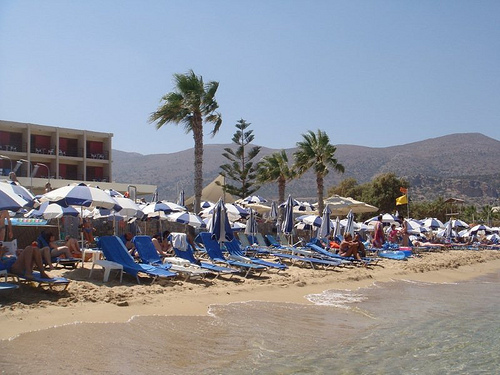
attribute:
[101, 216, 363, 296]
chairs — empty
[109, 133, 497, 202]
land — distant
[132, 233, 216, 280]
chair — blue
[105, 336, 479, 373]
water — clear, calm, shallow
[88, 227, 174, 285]
chair — blue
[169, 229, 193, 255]
towel — white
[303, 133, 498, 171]
mountain — large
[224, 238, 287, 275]
chair — blue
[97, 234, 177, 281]
beach chair — blue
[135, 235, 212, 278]
beach chair — blue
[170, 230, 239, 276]
beach chair — blue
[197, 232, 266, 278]
beach chair — blue, empty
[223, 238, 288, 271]
beach chair — blue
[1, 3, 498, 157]
sky — blue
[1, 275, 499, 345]
foam — white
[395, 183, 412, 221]
flag — yellow, red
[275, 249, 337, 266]
beach chair — blue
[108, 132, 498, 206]
mountain — brown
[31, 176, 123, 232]
parasol — blue, white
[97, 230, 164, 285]
beach chair — empty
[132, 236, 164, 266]
beach chair — empty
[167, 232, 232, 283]
beach chair — empty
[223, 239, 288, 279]
beach chair — empty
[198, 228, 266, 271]
chair — blue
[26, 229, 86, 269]
chair — blue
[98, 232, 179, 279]
chair — blue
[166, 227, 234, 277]
chair — blue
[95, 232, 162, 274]
towel — blue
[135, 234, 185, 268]
towel — blue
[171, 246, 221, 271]
towel — blue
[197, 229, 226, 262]
towel — blue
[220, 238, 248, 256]
towel — blue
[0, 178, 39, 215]
umbrella — blue, white, striped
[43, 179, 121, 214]
umbrella — blue, white, striped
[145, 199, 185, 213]
umbrella — blue, white, striped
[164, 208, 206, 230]
umbrella — blue, white, striped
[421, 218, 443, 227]
umbrella — blue, white, striped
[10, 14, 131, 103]
clouds — white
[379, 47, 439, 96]
clouds — white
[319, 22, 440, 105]
clouds — white